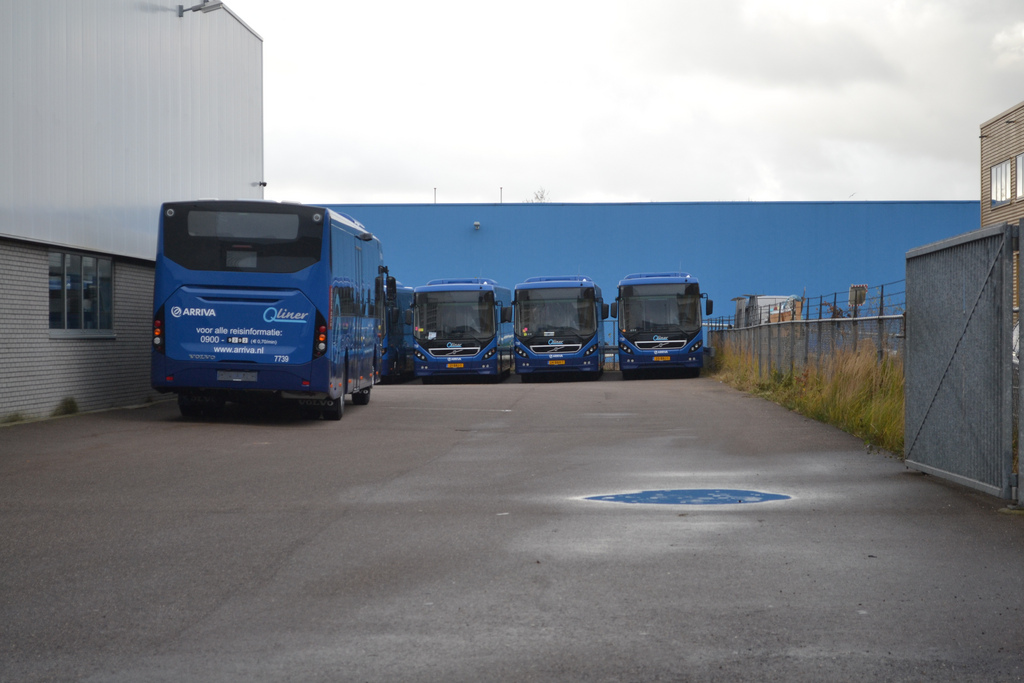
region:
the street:
[350, 531, 559, 652]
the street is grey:
[377, 555, 536, 666]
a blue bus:
[155, 209, 334, 377]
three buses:
[399, 277, 723, 360]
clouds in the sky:
[532, 49, 771, 163]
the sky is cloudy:
[635, 19, 832, 114]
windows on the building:
[47, 256, 125, 333]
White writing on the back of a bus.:
[139, 202, 348, 408]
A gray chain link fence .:
[708, 281, 934, 428]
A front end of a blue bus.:
[515, 274, 601, 374]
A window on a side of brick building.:
[44, 252, 124, 341]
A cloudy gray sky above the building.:
[275, 3, 980, 213]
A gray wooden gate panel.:
[897, 222, 1022, 498]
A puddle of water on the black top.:
[566, 478, 797, 510]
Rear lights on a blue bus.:
[147, 312, 335, 364]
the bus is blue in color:
[217, 282, 262, 322]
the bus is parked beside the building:
[126, 208, 219, 376]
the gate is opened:
[893, 237, 973, 454]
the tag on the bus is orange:
[539, 351, 577, 370]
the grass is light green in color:
[848, 371, 897, 429]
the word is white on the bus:
[166, 296, 220, 319]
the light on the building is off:
[172, 0, 223, 23]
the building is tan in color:
[983, 121, 1022, 153]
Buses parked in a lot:
[151, 183, 743, 460]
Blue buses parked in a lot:
[139, 193, 744, 419]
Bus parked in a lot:
[145, 184, 389, 409]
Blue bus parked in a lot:
[145, 190, 398, 424]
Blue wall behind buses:
[285, 198, 952, 351]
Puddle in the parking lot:
[565, 468, 804, 535]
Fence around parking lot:
[705, 307, 1015, 486]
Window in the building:
[31, 233, 133, 335]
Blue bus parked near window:
[147, 190, 391, 425]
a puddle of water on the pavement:
[581, 481, 782, 511]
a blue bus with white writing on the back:
[148, 200, 387, 419]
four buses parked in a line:
[384, 275, 711, 381]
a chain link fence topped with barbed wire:
[708, 278, 905, 397]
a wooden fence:
[900, 221, 1017, 503]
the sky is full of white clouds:
[224, 3, 1019, 206]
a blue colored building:
[326, 198, 979, 345]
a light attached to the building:
[174, 0, 220, 18]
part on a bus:
[142, 309, 168, 351]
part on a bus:
[305, 306, 334, 355]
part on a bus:
[167, 198, 317, 272]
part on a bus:
[318, 360, 360, 419]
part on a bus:
[411, 281, 494, 349]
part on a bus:
[620, 279, 704, 337]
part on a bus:
[522, 338, 592, 376]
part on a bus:
[622, 331, 698, 370]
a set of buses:
[79, 187, 797, 422]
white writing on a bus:
[172, 289, 229, 324]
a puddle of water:
[561, 456, 786, 514]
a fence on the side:
[706, 288, 926, 432]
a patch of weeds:
[760, 335, 910, 450]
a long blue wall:
[372, 187, 941, 299]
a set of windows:
[36, 250, 126, 340]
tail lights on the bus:
[302, 316, 335, 367]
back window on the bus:
[173, 199, 311, 247]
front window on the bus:
[507, 291, 606, 336]